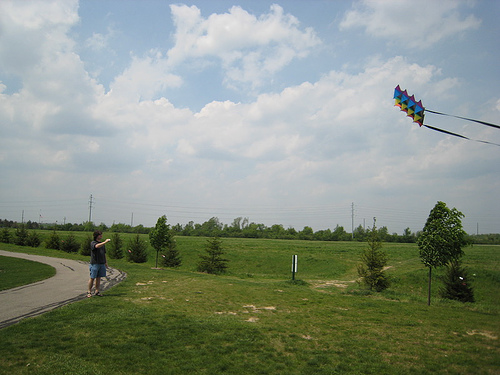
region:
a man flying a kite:
[86, 83, 498, 298]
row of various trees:
[0, 199, 499, 308]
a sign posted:
[289, 251, 300, 280]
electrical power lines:
[0, 192, 499, 242]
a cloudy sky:
[0, 0, 499, 236]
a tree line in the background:
[1, 213, 498, 245]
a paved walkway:
[1, 247, 128, 334]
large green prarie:
[1, 225, 498, 374]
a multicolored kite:
[392, 82, 499, 147]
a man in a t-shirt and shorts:
[86, 228, 113, 299]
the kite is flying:
[360, 62, 447, 150]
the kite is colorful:
[367, 72, 441, 145]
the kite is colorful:
[357, 56, 452, 178]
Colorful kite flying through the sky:
[385, 80, 499, 150]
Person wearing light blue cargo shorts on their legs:
[79, 228, 125, 301]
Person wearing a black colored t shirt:
[86, 228, 114, 268]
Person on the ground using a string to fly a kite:
[85, 54, 482, 316]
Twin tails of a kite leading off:
[424, 95, 497, 165]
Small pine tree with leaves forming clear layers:
[199, 227, 233, 279]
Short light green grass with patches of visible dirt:
[212, 286, 303, 339]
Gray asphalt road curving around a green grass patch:
[0, 246, 89, 328]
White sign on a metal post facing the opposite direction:
[286, 248, 302, 288]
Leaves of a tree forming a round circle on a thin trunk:
[413, 189, 464, 315]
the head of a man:
[79, 223, 116, 254]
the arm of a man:
[84, 238, 124, 259]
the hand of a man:
[96, 223, 126, 255]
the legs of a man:
[73, 257, 128, 302]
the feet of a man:
[82, 273, 129, 308]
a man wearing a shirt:
[80, 215, 131, 271]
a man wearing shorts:
[73, 250, 133, 286]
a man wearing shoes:
[68, 277, 122, 310]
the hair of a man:
[86, 226, 111, 245]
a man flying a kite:
[68, 77, 467, 302]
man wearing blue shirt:
[93, 251, 102, 258]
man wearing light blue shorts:
[89, 266, 99, 278]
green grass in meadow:
[125, 319, 167, 339]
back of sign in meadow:
[277, 245, 310, 282]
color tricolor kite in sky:
[389, 85, 431, 132]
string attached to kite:
[433, 100, 465, 149]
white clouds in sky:
[171, 107, 241, 140]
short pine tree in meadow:
[198, 236, 231, 284]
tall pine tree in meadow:
[415, 198, 456, 308]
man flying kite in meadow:
[86, 223, 121, 309]